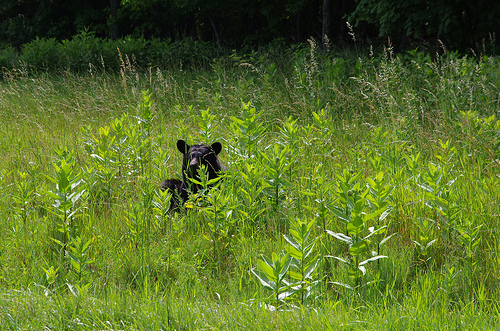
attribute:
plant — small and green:
[258, 131, 292, 239]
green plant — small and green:
[249, 257, 301, 312]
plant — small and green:
[256, 206, 334, 329]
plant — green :
[40, 147, 94, 289]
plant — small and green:
[62, 24, 103, 72]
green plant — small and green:
[323, 169, 385, 305]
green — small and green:
[138, 100, 163, 180]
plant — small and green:
[244, 245, 294, 312]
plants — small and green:
[415, 130, 462, 272]